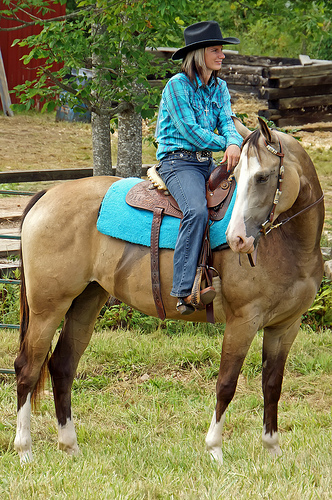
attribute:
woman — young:
[166, 20, 229, 313]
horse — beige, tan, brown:
[25, 137, 318, 376]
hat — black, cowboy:
[176, 22, 262, 49]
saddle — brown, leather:
[126, 175, 258, 218]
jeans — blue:
[163, 162, 201, 226]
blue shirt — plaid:
[170, 71, 223, 184]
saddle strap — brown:
[207, 151, 221, 196]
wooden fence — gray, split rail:
[263, 67, 320, 112]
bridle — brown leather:
[276, 177, 313, 237]